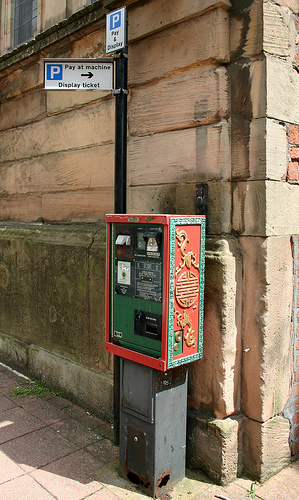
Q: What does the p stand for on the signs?
A: Parking.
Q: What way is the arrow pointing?
A: Right.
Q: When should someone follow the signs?
A: Pay for parking.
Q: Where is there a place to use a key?
A: Bottom machine.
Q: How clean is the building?
A: Dirty.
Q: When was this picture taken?
A: Daytime.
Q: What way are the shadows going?
A: Left.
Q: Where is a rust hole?
A: Bottom machine.